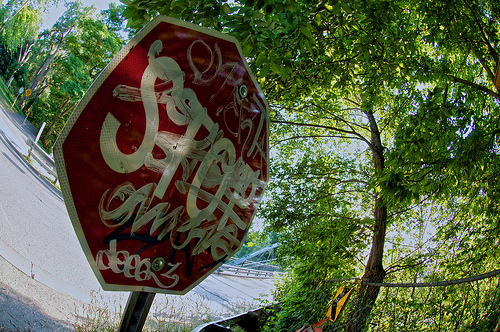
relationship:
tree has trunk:
[284, 12, 499, 303] [348, 262, 402, 331]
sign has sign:
[324, 263, 358, 331] [324, 279, 358, 321]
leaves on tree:
[272, 15, 334, 68] [284, 12, 499, 303]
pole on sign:
[126, 289, 157, 331] [79, 67, 281, 178]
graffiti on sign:
[150, 119, 253, 251] [79, 67, 281, 178]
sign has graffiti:
[79, 67, 281, 178] [150, 119, 253, 251]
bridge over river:
[226, 258, 286, 281] [235, 257, 272, 269]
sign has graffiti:
[79, 67, 281, 178] [96, 38, 251, 287]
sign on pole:
[79, 67, 281, 178] [126, 289, 157, 331]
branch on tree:
[269, 114, 353, 139] [284, 12, 499, 303]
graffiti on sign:
[96, 38, 251, 287] [79, 67, 281, 178]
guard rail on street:
[233, 260, 278, 272] [186, 254, 292, 315]